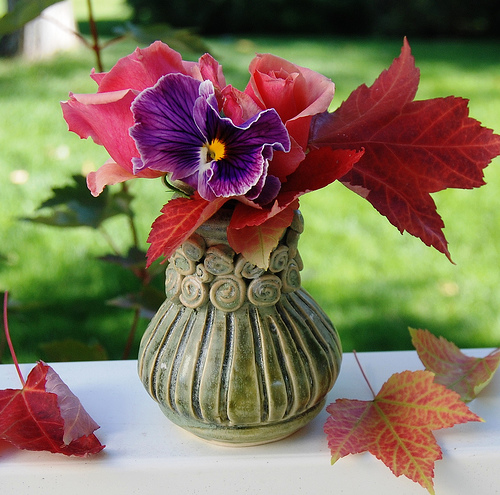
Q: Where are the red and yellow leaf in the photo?
A: On a white table.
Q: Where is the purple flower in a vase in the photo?
A: On the table.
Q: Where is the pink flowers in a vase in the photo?
A: On the table.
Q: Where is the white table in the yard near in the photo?
A: Near the green grass.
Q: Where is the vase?
A: Setting on table.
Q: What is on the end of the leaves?
A: Long red stems.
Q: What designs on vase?
A: Swirls design.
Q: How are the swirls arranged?
A: Around vase.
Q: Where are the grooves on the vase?
A: Below swirls.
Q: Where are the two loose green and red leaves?
A: Lying on table.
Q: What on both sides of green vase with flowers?
A: Red leaves.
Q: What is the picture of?
A: A vase and flowers.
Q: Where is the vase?
A: On a table.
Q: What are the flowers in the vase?
A: Roses and a purple flower.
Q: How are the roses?
A: Pink.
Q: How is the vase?
A: Green and decorative.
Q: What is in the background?
A: Green grass.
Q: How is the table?
A: White.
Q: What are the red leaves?
A: Maple.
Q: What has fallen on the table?
A: Three red leaves.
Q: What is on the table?
A: Leaf.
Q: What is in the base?
A: Purple flower.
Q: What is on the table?
A: A vase.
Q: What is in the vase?
A: Red leaf.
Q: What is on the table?
A: Leaves and vase.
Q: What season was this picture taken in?
A: Autumn.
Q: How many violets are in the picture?
A: One.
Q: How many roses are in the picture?
A: Two.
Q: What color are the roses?
A: Pink.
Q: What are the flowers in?
A: A vase.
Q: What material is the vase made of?
A: Clay.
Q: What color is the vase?
A: Green.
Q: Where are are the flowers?
A: In a vase.